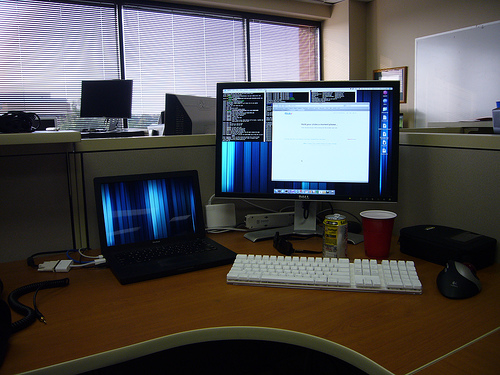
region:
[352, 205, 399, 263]
red plastic cup on desk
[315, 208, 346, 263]
open can behind keyboard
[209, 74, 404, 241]
computer monitor on desk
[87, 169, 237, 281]
open black laptop with lines on screen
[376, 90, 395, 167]
icons on computer screen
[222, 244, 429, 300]
white keyboard on desk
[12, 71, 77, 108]
white blinds on window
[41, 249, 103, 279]
cables plugged into laptop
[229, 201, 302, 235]
power strip next to wall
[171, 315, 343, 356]
round edge of desk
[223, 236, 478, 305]
keyboard is white and bulky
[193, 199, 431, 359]
keyboard is white and bulky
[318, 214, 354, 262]
Silver and yellow soda can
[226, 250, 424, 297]
White computer keyboard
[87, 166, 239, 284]
Black laptop with blue light screen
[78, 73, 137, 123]
Black desktop screen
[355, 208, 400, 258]
Red plastic cup with white inside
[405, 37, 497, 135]
White dry erase board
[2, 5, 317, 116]
Window with open blinds over it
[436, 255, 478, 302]
Black and silver computer mouse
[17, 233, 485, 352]
Brown work desk with computers on top of it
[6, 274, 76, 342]
Black cords on the edge of the desk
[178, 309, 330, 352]
curve on wood desk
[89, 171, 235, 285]
open black laptop on desk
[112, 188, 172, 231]
blue lines on laptop screen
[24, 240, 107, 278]
wires plugged into laptop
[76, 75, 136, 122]
computer screen in front of window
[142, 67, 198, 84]
white blinds on window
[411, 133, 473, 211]
wall of office cubicle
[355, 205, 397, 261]
red plastic cup with white rim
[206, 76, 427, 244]
computer screen is illuminated